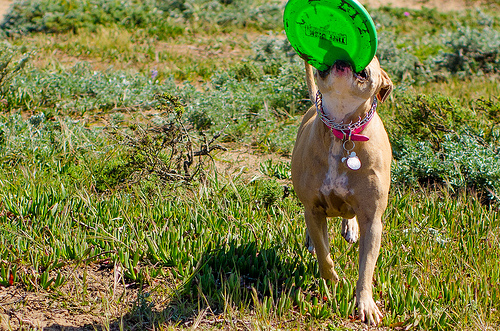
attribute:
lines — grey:
[207, 136, 298, 188]